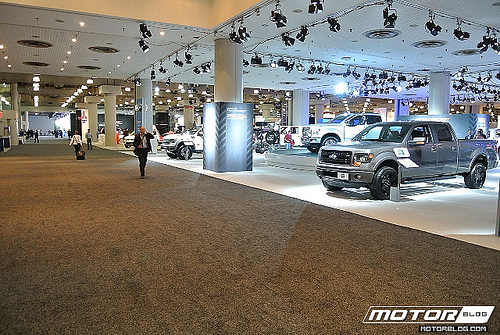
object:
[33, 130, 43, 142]
people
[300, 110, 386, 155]
truck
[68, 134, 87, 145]
shirt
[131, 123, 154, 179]
man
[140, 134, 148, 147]
shirt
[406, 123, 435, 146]
window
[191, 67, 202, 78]
lights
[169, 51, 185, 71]
lights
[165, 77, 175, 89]
lights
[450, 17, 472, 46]
lights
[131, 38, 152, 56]
lights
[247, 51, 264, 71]
lights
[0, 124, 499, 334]
carpet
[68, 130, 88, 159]
woman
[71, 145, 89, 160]
luggage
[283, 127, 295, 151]
person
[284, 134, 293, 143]
shirt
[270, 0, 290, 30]
light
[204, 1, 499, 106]
showroom ceiling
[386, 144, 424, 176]
label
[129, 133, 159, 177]
suit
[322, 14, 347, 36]
lights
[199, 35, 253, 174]
post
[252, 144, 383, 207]
pedestal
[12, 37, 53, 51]
air vent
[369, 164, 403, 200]
rim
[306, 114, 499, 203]
truck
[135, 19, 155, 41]
light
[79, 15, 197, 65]
room ceiling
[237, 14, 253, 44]
light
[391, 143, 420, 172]
display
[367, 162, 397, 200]
tire